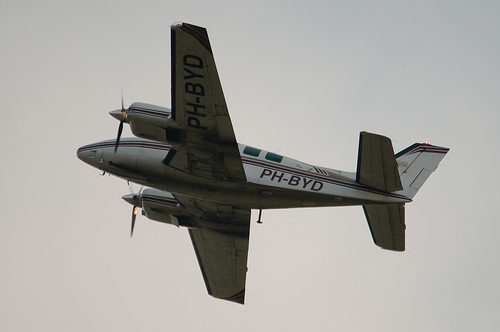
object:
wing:
[356, 129, 404, 192]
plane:
[73, 21, 450, 306]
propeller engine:
[110, 86, 129, 156]